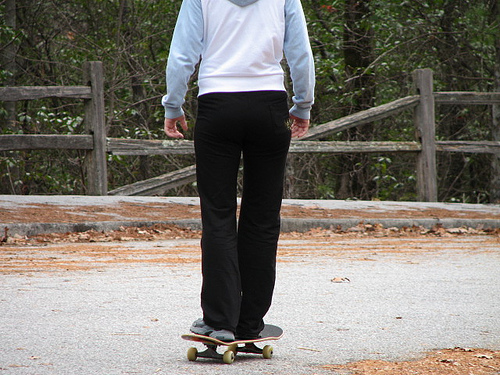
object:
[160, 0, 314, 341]
person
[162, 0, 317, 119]
shirt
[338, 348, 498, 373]
dead brush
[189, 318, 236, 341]
shoe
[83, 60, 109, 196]
post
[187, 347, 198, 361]
wheels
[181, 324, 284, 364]
skateboard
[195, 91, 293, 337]
pants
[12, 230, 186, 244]
leaves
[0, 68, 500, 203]
fence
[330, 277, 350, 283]
dead leaf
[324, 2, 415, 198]
dead tree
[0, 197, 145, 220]
pavement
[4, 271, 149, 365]
ground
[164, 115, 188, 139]
hand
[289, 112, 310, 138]
hand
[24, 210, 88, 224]
clay